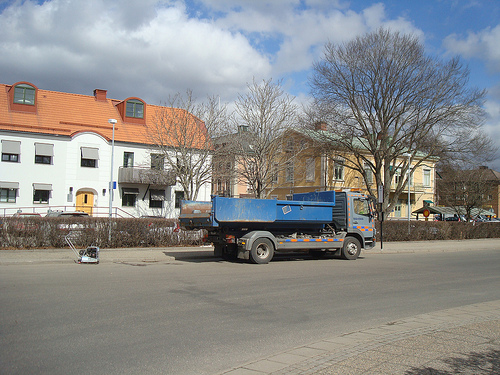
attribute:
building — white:
[0, 80, 213, 219]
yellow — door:
[76, 182, 96, 219]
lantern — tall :
[98, 116, 130, 131]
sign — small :
[374, 184, 388, 250]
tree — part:
[305, 45, 460, 200]